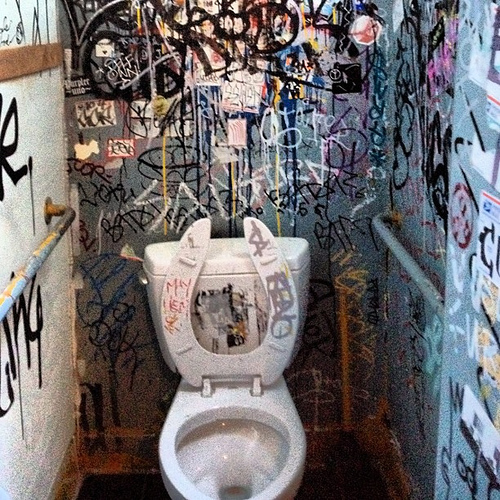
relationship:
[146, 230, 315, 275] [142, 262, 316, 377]
lid on tank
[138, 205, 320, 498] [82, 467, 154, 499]
toilet on floor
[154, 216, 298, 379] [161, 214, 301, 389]
grafitti on seat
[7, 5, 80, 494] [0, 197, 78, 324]
wall has hand rail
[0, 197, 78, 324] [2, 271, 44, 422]
hand rail has grafitti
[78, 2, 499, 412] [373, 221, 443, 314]
wall has hand rail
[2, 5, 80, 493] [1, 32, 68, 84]
wall has board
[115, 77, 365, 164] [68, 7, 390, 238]
wall has grafitti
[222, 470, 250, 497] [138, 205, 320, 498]
water in toilet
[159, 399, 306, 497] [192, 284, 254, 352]
bowl has grafitti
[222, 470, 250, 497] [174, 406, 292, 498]
water in bowl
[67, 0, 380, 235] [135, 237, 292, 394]
graffiti on seat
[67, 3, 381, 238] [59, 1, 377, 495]
graffiti on wall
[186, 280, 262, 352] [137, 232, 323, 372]
graffiti on tank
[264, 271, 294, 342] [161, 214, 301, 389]
graffiti on seat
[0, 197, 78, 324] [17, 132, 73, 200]
hand rail on wall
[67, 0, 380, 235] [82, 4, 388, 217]
graffiti on wall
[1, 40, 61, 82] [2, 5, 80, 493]
board on wall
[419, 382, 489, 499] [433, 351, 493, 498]
drawing resemples bart simpson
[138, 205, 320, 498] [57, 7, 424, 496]
toilet against wall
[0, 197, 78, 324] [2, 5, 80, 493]
hand rail on wall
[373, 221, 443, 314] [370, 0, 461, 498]
hand rail on wall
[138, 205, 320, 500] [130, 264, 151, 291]
toilet has flusher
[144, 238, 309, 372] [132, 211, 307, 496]
tank on toilet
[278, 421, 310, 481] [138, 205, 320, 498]
rim on toilet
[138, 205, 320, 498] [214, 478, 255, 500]
toilet has drain hole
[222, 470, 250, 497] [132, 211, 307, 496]
water on toilet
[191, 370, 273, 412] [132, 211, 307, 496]
hinges of a toilet